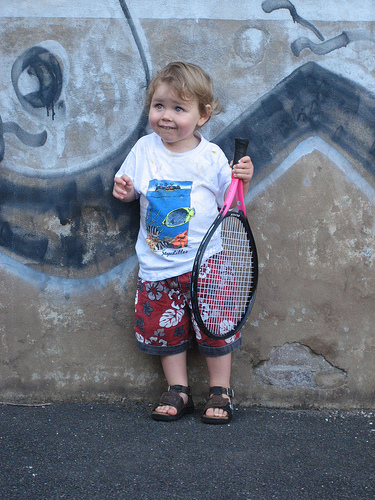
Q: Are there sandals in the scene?
A: Yes, there are sandals.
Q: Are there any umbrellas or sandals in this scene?
A: Yes, there are sandals.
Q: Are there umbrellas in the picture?
A: No, there are no umbrellas.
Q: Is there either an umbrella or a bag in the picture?
A: No, there are no umbrellas or bags.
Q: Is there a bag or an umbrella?
A: No, there are no umbrellas or bags.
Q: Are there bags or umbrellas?
A: No, there are no umbrellas or bags.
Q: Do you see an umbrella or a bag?
A: No, there are no umbrellas or bags.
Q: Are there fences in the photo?
A: No, there are no fences.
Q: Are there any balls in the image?
A: No, there are no balls.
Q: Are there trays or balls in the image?
A: No, there are no balls or trays.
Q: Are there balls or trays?
A: No, there are no balls or trays.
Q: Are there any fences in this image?
A: No, there are no fences.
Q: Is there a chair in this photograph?
A: No, there are no chairs.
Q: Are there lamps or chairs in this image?
A: No, there are no chairs or lamps.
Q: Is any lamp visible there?
A: No, there are no lamps.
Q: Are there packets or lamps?
A: No, there are no lamps or packets.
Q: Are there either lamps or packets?
A: No, there are no lamps or packets.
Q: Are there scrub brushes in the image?
A: No, there are no scrub brushes.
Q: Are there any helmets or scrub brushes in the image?
A: No, there are no scrub brushes or helmets.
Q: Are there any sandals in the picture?
A: Yes, there are sandals.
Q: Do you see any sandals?
A: Yes, there are sandals.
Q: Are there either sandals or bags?
A: Yes, there are sandals.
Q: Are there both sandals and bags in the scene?
A: No, there are sandals but no bags.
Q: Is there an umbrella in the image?
A: No, there are no umbrellas.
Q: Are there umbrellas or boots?
A: No, there are no umbrellas or boots.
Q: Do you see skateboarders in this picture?
A: No, there are no skateboarders.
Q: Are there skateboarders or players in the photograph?
A: No, there are no skateboarders or players.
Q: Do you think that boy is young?
A: Yes, the boy is young.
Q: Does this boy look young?
A: Yes, the boy is young.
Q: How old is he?
A: The boy is young.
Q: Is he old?
A: No, the boy is young.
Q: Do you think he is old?
A: No, the boy is young.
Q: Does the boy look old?
A: No, the boy is young.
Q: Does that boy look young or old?
A: The boy is young.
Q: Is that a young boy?
A: Yes, that is a young boy.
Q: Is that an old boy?
A: No, that is a young boy.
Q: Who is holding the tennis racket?
A: The boy is holding the tennis racket.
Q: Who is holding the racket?
A: The boy is holding the tennis racket.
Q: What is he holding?
A: The boy is holding the racket.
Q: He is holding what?
A: The boy is holding the racket.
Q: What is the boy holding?
A: The boy is holding the racket.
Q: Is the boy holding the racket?
A: Yes, the boy is holding the racket.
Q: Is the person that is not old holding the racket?
A: Yes, the boy is holding the racket.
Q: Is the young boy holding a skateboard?
A: No, the boy is holding the racket.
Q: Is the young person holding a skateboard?
A: No, the boy is holding the racket.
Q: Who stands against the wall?
A: The boy stands against the wall.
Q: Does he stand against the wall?
A: Yes, the boy stands against the wall.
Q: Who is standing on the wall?
A: The boy is standing on the wall.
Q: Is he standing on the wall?
A: Yes, the boy is standing on the wall.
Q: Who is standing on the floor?
A: The boy is standing on the floor.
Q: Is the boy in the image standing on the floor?
A: Yes, the boy is standing on the floor.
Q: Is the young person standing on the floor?
A: Yes, the boy is standing on the floor.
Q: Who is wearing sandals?
A: The boy is wearing sandals.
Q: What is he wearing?
A: The boy is wearing sandals.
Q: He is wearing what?
A: The boy is wearing sandals.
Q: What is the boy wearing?
A: The boy is wearing sandals.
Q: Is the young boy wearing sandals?
A: Yes, the boy is wearing sandals.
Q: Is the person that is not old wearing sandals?
A: Yes, the boy is wearing sandals.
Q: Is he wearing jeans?
A: No, the boy is wearing sandals.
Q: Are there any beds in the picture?
A: No, there are no beds.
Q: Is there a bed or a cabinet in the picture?
A: No, there are no beds or cabinets.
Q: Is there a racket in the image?
A: Yes, there is a racket.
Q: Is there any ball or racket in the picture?
A: Yes, there is a racket.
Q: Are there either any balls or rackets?
A: Yes, there is a racket.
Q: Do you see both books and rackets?
A: No, there is a racket but no books.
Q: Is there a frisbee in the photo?
A: No, there are no frisbees.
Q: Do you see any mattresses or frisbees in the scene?
A: No, there are no frisbees or mattresses.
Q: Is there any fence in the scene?
A: No, there are no fences.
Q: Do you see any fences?
A: No, there are no fences.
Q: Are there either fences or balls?
A: No, there are no fences or balls.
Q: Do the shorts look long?
A: Yes, the shorts are long.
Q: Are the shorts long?
A: Yes, the shorts are long.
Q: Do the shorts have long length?
A: Yes, the shorts are long.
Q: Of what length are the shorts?
A: The shorts are long.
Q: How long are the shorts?
A: The shorts are long.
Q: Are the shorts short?
A: No, the shorts are long.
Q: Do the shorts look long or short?
A: The shorts are long.